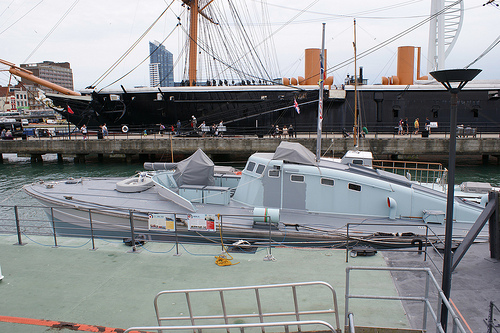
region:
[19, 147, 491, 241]
the boat at the dock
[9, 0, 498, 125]
the ship is docked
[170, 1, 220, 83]
the mast on the ship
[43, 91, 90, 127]
the bow of the ship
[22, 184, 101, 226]
the bow of the boat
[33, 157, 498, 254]
the boat being painted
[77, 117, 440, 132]
people on the dock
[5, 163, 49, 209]
the water is calm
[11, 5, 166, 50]
the sky is gray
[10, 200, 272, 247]
the fence beside the boat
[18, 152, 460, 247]
a white yacht on a pier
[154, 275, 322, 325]
a small white gate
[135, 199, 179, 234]
a small white sign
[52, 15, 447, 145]
a large black ocean ship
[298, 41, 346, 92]
large orange ship pipes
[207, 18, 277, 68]
a bunch of boat strings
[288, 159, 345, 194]
windows on a yacht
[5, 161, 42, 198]
a bunch of still ocean water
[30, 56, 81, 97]
a tall grey building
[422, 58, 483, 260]
a tall black light post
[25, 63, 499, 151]
the ship is black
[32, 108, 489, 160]
people at the dock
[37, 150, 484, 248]
white boat that is docked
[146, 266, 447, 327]
white railings to the entrance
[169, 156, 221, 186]
gray covers over the part of boat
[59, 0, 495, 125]
larger ship in the back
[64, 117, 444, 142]
people on the pier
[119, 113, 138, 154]
white life perserve hanging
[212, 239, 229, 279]
yellow rope on the ground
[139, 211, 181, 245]
sign on the rail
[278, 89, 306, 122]
flag in the distance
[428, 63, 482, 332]
black light post by the rail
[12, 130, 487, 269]
boat docked at the pier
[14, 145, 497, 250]
small white boat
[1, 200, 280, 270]
railing along the pier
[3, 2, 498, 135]
large ship in the water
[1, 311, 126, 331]
orange line on the ground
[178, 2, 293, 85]
several ropes on the ship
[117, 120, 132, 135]
small white life preserver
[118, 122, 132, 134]
life preserver on the side of the ship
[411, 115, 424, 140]
man walking along the pier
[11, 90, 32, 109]
windows on the building